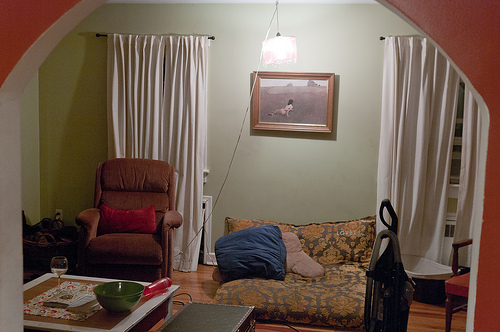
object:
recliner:
[73, 157, 182, 279]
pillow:
[98, 203, 157, 232]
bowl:
[93, 279, 143, 313]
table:
[23, 270, 181, 331]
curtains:
[101, 32, 210, 273]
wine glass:
[49, 254, 68, 294]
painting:
[246, 69, 335, 133]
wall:
[37, 0, 440, 252]